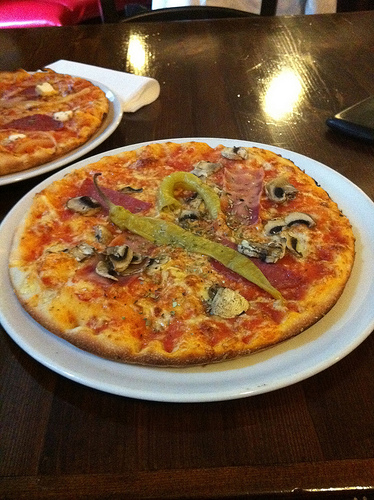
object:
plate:
[0, 69, 125, 185]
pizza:
[7, 139, 357, 368]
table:
[0, 7, 373, 500]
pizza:
[1, 69, 108, 176]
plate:
[0, 135, 374, 403]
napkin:
[44, 58, 161, 113]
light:
[260, 53, 310, 110]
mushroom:
[266, 179, 296, 205]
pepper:
[156, 172, 220, 221]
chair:
[95, 1, 281, 24]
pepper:
[92, 172, 286, 304]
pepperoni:
[79, 176, 153, 215]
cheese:
[47, 259, 67, 275]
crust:
[15, 233, 20, 260]